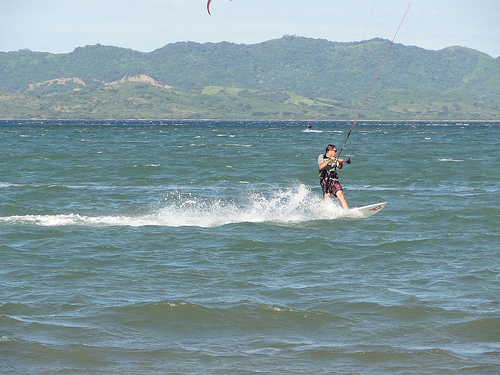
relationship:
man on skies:
[316, 144, 344, 211] [340, 198, 391, 217]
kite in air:
[201, 0, 219, 19] [102, 8, 426, 45]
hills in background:
[0, 36, 499, 121] [6, 3, 490, 120]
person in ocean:
[293, 119, 322, 136] [76, 93, 336, 282]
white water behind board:
[3, 183, 345, 228] [347, 201, 389, 221]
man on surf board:
[316, 144, 344, 211] [328, 193, 390, 225]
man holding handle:
[316, 144, 344, 211] [329, 152, 342, 169]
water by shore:
[2, 118, 499, 370] [0, 37, 498, 118]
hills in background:
[0, 36, 499, 121] [2, 10, 491, 126]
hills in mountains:
[31, 75, 158, 89] [268, 29, 488, 74]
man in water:
[316, 144, 344, 211] [2, 118, 499, 370]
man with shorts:
[316, 144, 344, 211] [320, 178, 344, 196]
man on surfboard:
[316, 144, 344, 211] [335, 198, 390, 220]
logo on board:
[349, 205, 396, 226] [348, 200, 393, 218]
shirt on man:
[316, 150, 341, 178] [316, 144, 344, 211]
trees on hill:
[21, 43, 362, 113] [0, 32, 498, 136]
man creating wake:
[316, 129, 357, 174] [346, 194, 386, 221]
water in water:
[2, 118, 499, 370] [50, 128, 205, 298]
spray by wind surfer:
[161, 173, 276, 235] [318, 133, 347, 211]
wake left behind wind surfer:
[0, 190, 325, 233] [317, 137, 353, 214]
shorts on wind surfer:
[320, 172, 342, 197] [318, 144, 350, 210]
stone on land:
[26, 72, 176, 92] [0, 32, 499, 124]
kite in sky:
[206, 0, 219, 21] [0, 0, 498, 51]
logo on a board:
[370, 201, 385, 217] [318, 198, 399, 218]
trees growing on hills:
[0, 35, 500, 119] [37, 39, 475, 119]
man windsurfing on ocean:
[316, 144, 344, 211] [55, 139, 476, 301]